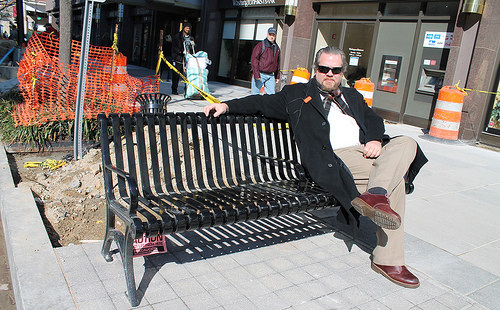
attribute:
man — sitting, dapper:
[208, 40, 432, 287]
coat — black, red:
[230, 79, 373, 232]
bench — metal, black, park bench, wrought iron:
[99, 106, 364, 298]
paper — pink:
[135, 229, 168, 258]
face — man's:
[313, 53, 346, 92]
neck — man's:
[315, 84, 347, 100]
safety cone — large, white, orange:
[424, 84, 467, 144]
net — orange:
[16, 35, 120, 127]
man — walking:
[248, 25, 283, 97]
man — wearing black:
[170, 20, 195, 94]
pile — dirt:
[30, 116, 235, 239]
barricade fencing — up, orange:
[13, 28, 143, 128]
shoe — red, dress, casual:
[375, 258, 420, 290]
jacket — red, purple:
[252, 42, 284, 82]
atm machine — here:
[416, 63, 441, 91]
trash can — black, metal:
[132, 90, 174, 112]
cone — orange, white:
[427, 80, 466, 138]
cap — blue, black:
[270, 28, 279, 35]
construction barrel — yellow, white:
[425, 86, 469, 145]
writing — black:
[138, 237, 165, 251]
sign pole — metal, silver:
[71, 1, 99, 165]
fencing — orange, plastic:
[13, 36, 136, 129]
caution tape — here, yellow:
[145, 41, 225, 107]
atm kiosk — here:
[414, 63, 439, 95]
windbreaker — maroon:
[252, 42, 281, 78]